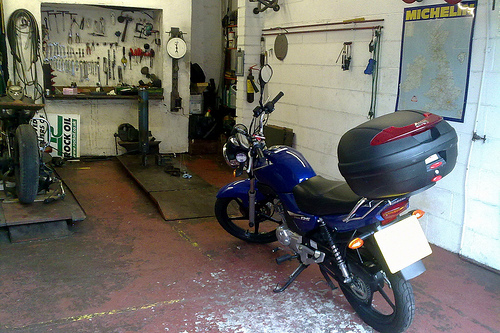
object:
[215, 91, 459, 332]
motorcycle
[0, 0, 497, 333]
garage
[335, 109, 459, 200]
cargo container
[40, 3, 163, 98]
tools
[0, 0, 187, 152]
wall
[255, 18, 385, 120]
tools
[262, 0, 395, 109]
wall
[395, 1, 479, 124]
sign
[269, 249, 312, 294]
kickstand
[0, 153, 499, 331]
garage floor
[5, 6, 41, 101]
wires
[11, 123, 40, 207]
tire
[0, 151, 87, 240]
rack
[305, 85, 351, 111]
cement brick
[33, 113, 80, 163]
sign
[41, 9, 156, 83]
array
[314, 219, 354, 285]
shock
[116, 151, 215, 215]
lift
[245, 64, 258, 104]
fire extinguisher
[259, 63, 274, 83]
mirror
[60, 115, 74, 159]
rock oil